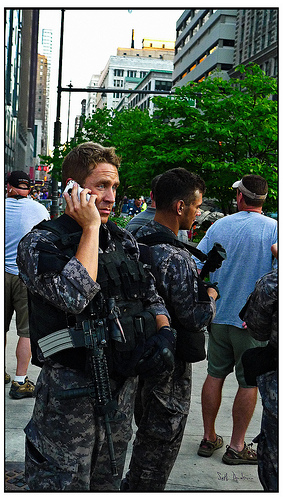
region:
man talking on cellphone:
[27, 141, 168, 485]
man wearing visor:
[205, 170, 268, 459]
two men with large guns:
[33, 141, 196, 499]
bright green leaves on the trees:
[54, 66, 276, 203]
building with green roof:
[116, 61, 167, 113]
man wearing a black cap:
[7, 171, 47, 405]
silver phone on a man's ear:
[62, 180, 97, 209]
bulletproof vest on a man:
[32, 215, 146, 373]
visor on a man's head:
[230, 176, 272, 202]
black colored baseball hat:
[5, 169, 33, 192]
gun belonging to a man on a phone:
[36, 290, 123, 481]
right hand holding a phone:
[60, 184, 104, 229]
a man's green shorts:
[206, 313, 266, 387]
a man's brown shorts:
[5, 268, 38, 335]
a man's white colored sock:
[12, 372, 27, 382]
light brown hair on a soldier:
[61, 139, 122, 190]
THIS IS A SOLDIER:
[125, 174, 206, 496]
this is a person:
[5, 173, 42, 398]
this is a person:
[118, 189, 134, 215]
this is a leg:
[193, 366, 226, 459]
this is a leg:
[221, 377, 260, 472]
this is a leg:
[8, 327, 43, 407]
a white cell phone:
[61, 180, 91, 205]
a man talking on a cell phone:
[16, 140, 175, 490]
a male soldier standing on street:
[17, 142, 177, 491]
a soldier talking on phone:
[16, 142, 174, 489]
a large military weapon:
[36, 296, 121, 477]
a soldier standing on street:
[133, 167, 224, 492]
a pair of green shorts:
[205, 318, 263, 386]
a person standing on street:
[191, 174, 277, 464]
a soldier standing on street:
[237, 239, 277, 490]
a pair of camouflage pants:
[23, 362, 137, 494]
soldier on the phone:
[34, 134, 145, 282]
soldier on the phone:
[56, 152, 122, 257]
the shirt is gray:
[197, 206, 270, 336]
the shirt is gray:
[199, 205, 270, 329]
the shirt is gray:
[197, 200, 281, 341]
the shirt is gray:
[195, 203, 271, 327]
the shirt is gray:
[192, 203, 262, 345]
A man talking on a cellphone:
[57, 140, 120, 224]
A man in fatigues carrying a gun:
[15, 142, 177, 489]